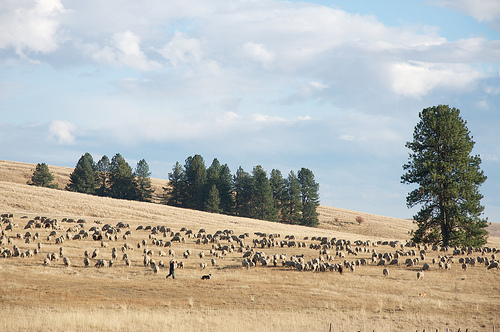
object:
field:
[1, 157, 497, 330]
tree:
[400, 106, 490, 252]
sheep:
[210, 256, 214, 267]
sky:
[0, 0, 499, 221]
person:
[165, 258, 177, 279]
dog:
[199, 272, 214, 280]